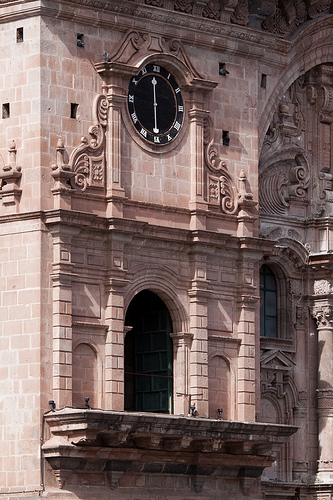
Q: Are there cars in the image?
A: No, there are no cars.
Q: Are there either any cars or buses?
A: No, there are no cars or buses.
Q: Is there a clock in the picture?
A: Yes, there is a clock.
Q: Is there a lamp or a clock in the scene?
A: Yes, there is a clock.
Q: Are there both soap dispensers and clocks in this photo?
A: No, there is a clock but no soap dispensers.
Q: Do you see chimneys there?
A: No, there are no chimneys.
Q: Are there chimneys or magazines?
A: No, there are no chimneys or magazines.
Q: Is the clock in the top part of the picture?
A: Yes, the clock is in the top of the image.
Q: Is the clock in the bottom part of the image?
A: No, the clock is in the top of the image.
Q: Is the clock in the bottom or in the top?
A: The clock is in the top of the image.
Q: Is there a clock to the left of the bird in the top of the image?
A: Yes, there is a clock to the left of the bird.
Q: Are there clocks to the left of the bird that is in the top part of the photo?
A: Yes, there is a clock to the left of the bird.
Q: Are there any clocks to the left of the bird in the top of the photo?
A: Yes, there is a clock to the left of the bird.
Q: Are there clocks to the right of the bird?
A: No, the clock is to the left of the bird.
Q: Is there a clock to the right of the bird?
A: No, the clock is to the left of the bird.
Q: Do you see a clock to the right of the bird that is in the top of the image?
A: No, the clock is to the left of the bird.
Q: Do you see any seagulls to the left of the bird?
A: No, there is a clock to the left of the bird.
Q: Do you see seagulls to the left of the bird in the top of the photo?
A: No, there is a clock to the left of the bird.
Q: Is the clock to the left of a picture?
A: No, the clock is to the left of the bird.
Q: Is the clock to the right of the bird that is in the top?
A: No, the clock is to the left of the bird.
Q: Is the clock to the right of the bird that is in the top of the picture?
A: No, the clock is to the left of the bird.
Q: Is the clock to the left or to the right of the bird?
A: The clock is to the left of the bird.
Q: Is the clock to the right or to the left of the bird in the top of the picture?
A: The clock is to the left of the bird.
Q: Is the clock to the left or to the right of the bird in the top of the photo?
A: The clock is to the left of the bird.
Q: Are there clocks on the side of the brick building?
A: Yes, there is a clock on the side of the building.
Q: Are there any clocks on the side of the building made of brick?
A: Yes, there is a clock on the side of the building.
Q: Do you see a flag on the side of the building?
A: No, there is a clock on the side of the building.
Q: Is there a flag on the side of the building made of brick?
A: No, there is a clock on the side of the building.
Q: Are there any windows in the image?
A: Yes, there is a window.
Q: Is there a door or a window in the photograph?
A: Yes, there is a window.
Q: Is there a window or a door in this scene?
A: Yes, there is a window.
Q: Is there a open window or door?
A: Yes, there is an open window.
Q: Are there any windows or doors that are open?
A: Yes, the window is open.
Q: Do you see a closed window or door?
A: Yes, there is a closed window.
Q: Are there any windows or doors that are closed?
A: Yes, the window is closed.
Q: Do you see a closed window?
A: Yes, there is a closed window.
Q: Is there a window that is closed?
A: Yes, there is a window that is closed.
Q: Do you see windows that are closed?
A: Yes, there is a window that is closed.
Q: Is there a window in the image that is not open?
A: Yes, there is an closed window.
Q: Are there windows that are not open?
A: Yes, there is an closed window.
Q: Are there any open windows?
A: Yes, there is an open window.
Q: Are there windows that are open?
A: Yes, there is a window that is open.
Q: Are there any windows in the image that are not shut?
A: Yes, there is a open window.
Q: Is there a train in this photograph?
A: No, there are no trains.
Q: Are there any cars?
A: No, there are no cars.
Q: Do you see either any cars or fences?
A: No, there are no cars or fences.